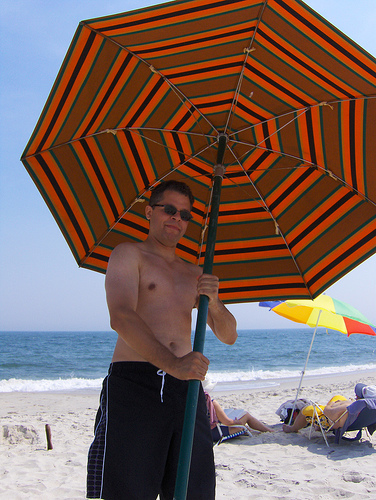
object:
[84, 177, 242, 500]
man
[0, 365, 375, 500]
beach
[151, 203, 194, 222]
glasses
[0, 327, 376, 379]
water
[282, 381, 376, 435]
person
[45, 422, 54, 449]
stick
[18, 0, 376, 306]
umbrella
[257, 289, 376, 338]
umbrella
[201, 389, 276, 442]
female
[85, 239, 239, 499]
trunks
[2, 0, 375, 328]
sky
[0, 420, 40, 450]
footstep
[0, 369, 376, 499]
sand